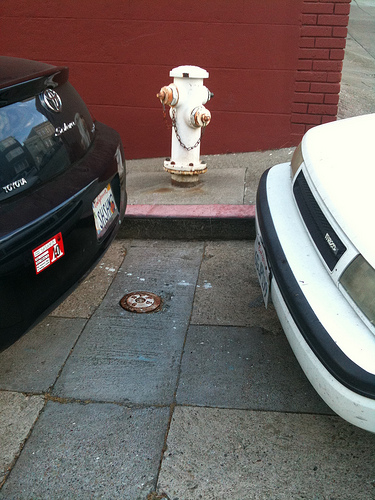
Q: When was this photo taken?
A: During the day.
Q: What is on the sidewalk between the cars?
A: A fire hydrant.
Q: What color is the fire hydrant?
A: White.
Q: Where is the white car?
A: On the right.